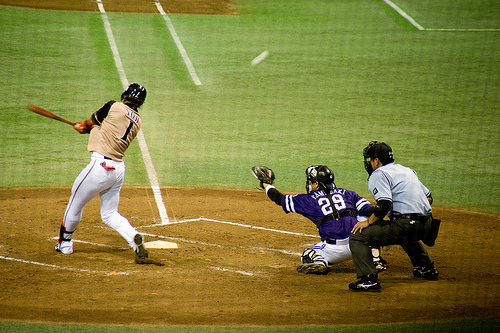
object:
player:
[26, 81, 151, 264]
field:
[0, 2, 497, 332]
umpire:
[347, 140, 439, 294]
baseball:
[248, 49, 271, 71]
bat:
[25, 104, 100, 138]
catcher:
[248, 163, 391, 274]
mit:
[249, 163, 274, 187]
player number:
[118, 113, 139, 142]